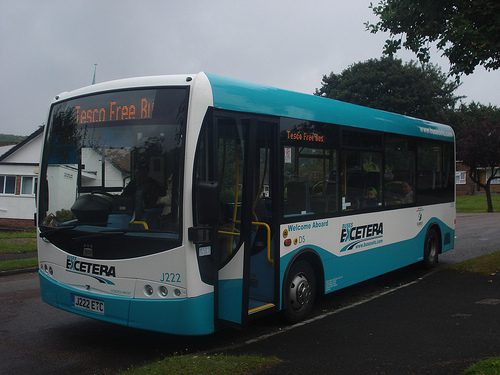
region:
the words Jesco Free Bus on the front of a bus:
[74, 100, 159, 122]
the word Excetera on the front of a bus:
[65, 255, 120, 277]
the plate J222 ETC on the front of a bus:
[70, 290, 110, 313]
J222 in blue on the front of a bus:
[158, 263, 183, 285]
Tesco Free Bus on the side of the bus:
[275, 117, 326, 146]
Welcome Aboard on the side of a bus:
[285, 222, 339, 229]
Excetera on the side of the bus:
[339, 223, 385, 238]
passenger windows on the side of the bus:
[285, 142, 455, 206]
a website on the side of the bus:
[410, 117, 456, 140]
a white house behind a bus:
[7, 110, 44, 241]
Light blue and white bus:
[37, 65, 477, 337]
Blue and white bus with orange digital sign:
[28, 66, 483, 341]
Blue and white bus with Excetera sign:
[27, 72, 487, 347]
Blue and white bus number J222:
[26, 72, 464, 337]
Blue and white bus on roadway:
[21, 52, 486, 362]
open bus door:
[165, 32, 341, 353]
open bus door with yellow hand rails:
[151, 52, 341, 342]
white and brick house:
[0, 85, 96, 285]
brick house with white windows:
[392, 67, 497, 244]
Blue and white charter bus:
[29, 54, 482, 344]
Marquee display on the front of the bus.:
[71, 100, 153, 116]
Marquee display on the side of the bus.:
[279, 127, 336, 142]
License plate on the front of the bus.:
[72, 295, 107, 316]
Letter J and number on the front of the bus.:
[154, 267, 187, 288]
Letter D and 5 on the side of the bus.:
[297, 235, 304, 246]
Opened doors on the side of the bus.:
[222, 110, 285, 327]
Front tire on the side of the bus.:
[282, 242, 321, 322]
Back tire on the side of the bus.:
[418, 221, 443, 263]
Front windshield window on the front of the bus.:
[37, 85, 189, 252]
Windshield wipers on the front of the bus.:
[34, 206, 139, 252]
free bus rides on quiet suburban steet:
[56, 27, 473, 335]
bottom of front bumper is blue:
[33, 283, 223, 340]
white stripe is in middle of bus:
[265, 195, 460, 267]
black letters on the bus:
[331, 217, 393, 246]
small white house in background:
[2, 106, 40, 298]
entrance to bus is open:
[208, 105, 293, 329]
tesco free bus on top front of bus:
[64, 92, 179, 137]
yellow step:
[229, 297, 282, 316]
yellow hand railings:
[215, 175, 277, 267]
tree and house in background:
[449, 89, 494, 236]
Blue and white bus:
[33, 70, 475, 332]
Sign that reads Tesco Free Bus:
[69, 93, 171, 130]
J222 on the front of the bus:
[156, 266, 186, 288]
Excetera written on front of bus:
[58, 249, 124, 281]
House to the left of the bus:
[0, 107, 38, 244]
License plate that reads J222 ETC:
[68, 290, 115, 326]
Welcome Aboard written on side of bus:
[285, 220, 334, 231]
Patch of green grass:
[119, 347, 284, 373]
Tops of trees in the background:
[326, 46, 498, 121]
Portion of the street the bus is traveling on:
[3, 322, 101, 374]